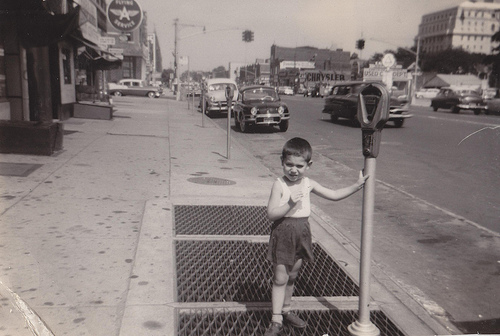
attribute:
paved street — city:
[304, 98, 499, 274]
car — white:
[194, 72, 240, 117]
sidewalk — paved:
[11, 104, 238, 334]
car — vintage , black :
[228, 79, 293, 141]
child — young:
[245, 130, 368, 332]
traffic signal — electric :
[242, 28, 254, 42]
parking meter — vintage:
[349, 83, 391, 334]